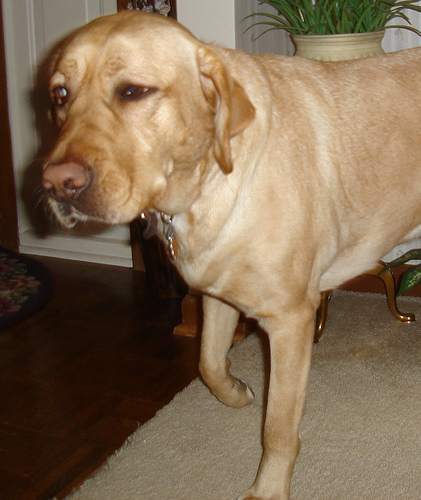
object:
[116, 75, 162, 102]
eye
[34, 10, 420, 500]
dog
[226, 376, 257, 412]
paw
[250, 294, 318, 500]
leg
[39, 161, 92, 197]
nose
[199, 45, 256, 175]
ear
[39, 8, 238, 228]
head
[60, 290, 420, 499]
carpet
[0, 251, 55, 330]
rug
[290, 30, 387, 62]
pot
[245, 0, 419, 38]
plant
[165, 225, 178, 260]
tag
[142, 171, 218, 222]
collar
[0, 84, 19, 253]
door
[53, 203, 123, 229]
mouth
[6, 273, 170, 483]
floor